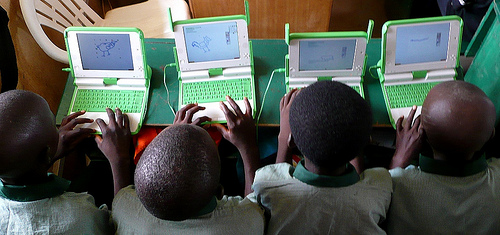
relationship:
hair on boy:
[289, 82, 369, 159] [386, 80, 499, 234]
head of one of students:
[0, 90, 60, 181] [388, 77, 495, 232]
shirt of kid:
[248, 157, 393, 233] [255, 80, 391, 232]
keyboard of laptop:
[378, 62, 464, 107] [49, 12, 153, 135]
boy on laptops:
[0, 89, 133, 234] [58, 33, 480, 81]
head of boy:
[418, 80, 496, 168] [0, 89, 133, 234]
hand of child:
[389, 104, 424, 168] [374, 75, 499, 232]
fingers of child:
[396, 103, 428, 138] [396, 78, 498, 233]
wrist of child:
[233, 137, 260, 153] [0, 76, 108, 233]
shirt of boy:
[390, 165, 498, 233] [0, 89, 133, 234]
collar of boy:
[293, 164, 361, 187] [113, 95, 268, 233]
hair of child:
[289, 82, 369, 159] [254, 80, 391, 230]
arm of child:
[99, 156, 154, 200] [5, 79, 149, 229]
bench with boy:
[4, 7, 344, 131] [251, 76, 395, 233]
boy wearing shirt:
[0, 87, 134, 234] [1, 174, 114, 234]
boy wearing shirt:
[113, 92, 268, 234] [111, 182, 268, 233]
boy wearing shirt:
[251, 76, 395, 233] [248, 157, 393, 233]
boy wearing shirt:
[386, 77, 498, 234] [391, 151, 499, 233]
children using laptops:
[2, 82, 498, 229] [54, 10, 497, 116]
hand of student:
[393, 106, 425, 154] [378, 77, 499, 232]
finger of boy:
[215, 122, 227, 136] [113, 95, 268, 233]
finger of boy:
[229, 94, 240, 116] [113, 95, 268, 233]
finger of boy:
[220, 100, 231, 123] [113, 95, 268, 233]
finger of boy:
[245, 101, 250, 118] [113, 95, 268, 233]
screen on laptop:
[183, 20, 240, 64] [165, 7, 257, 127]